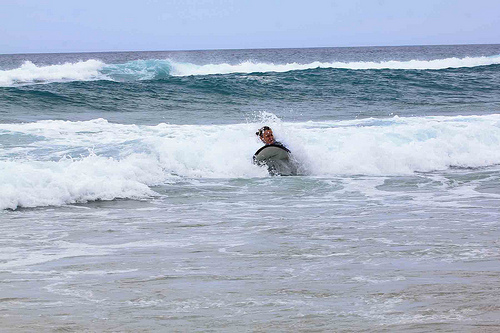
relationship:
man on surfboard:
[242, 107, 289, 147] [253, 141, 298, 176]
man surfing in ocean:
[242, 107, 289, 147] [1, 42, 499, 331]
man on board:
[242, 107, 289, 147] [240, 142, 302, 173]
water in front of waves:
[320, 186, 496, 324] [76, 40, 253, 80]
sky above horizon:
[2, 6, 498, 38] [0, 38, 498, 51]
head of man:
[249, 117, 276, 130] [242, 107, 289, 147]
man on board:
[242, 107, 289, 147] [246, 144, 310, 180]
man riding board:
[242, 107, 289, 147] [256, 142, 299, 174]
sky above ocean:
[2, 6, 498, 38] [51, 167, 487, 332]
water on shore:
[201, 248, 375, 329] [6, 22, 498, 330]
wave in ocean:
[74, 38, 226, 106] [30, 73, 490, 332]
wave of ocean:
[28, 107, 439, 172] [1, 42, 499, 331]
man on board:
[242, 107, 289, 147] [243, 140, 304, 155]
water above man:
[57, 120, 276, 240] [242, 118, 288, 152]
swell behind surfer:
[20, 63, 496, 141] [248, 114, 321, 195]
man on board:
[242, 107, 289, 147] [258, 141, 332, 192]